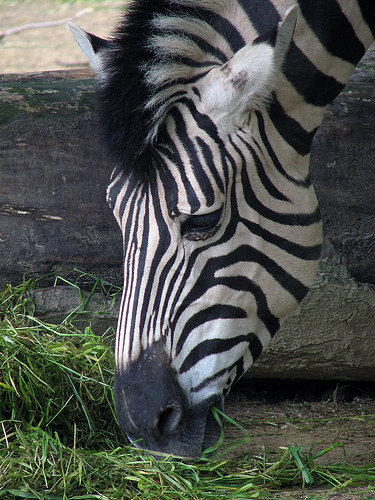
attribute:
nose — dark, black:
[110, 370, 211, 448]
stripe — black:
[273, 103, 297, 137]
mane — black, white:
[109, 30, 182, 102]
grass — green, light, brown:
[30, 334, 89, 402]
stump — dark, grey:
[28, 280, 100, 325]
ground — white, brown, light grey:
[11, 445, 97, 492]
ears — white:
[68, 3, 311, 104]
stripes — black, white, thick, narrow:
[153, 159, 239, 195]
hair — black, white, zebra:
[217, 50, 264, 97]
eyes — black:
[170, 203, 237, 233]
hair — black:
[293, 63, 311, 90]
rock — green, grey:
[45, 280, 83, 327]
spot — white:
[168, 64, 196, 82]